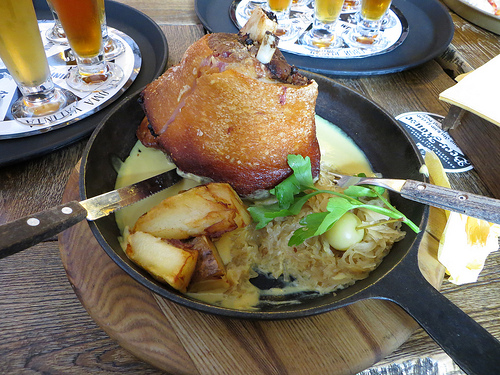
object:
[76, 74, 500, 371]
skillet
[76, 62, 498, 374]
pan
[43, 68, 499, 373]
board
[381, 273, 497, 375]
handle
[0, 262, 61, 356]
zebra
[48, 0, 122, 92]
glass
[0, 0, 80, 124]
glass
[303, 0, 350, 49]
glass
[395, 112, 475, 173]
coaster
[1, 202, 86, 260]
handle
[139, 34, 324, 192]
meat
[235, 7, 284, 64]
bone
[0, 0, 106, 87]
beer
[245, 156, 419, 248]
parsley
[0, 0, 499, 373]
table top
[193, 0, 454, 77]
tray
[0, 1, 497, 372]
table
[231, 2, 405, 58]
drinks tray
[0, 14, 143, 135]
drinks tray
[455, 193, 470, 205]
screw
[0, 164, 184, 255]
knife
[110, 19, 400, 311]
food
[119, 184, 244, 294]
potatoes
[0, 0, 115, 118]
drinks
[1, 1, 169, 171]
tray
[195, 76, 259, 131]
skin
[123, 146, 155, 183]
sauce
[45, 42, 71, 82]
paper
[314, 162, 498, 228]
fork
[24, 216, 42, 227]
circle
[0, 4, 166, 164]
platters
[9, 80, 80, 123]
trey